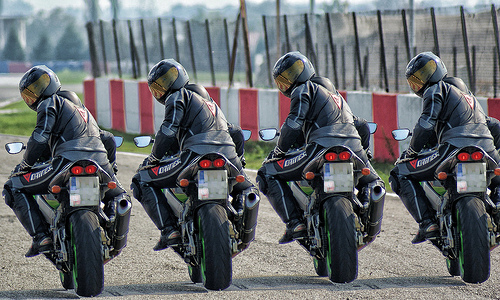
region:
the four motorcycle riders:
[19, 61, 499, 273]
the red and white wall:
[88, 74, 499, 171]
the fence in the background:
[86, 22, 496, 91]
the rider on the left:
[12, 61, 135, 288]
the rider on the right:
[393, 56, 498, 266]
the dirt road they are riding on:
[0, 133, 495, 299]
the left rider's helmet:
[19, 72, 64, 104]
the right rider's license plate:
[452, 158, 492, 198]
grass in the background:
[7, 75, 394, 189]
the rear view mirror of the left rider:
[3, 140, 24, 155]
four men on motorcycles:
[10, 40, 494, 291]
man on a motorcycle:
[17, 47, 131, 290]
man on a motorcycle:
[130, 41, 278, 287]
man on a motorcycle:
[257, 40, 392, 282]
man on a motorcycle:
[395, 28, 498, 285]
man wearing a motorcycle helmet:
[2, 56, 74, 118]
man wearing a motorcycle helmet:
[137, 45, 202, 119]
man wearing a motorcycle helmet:
[265, 45, 331, 135]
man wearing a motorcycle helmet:
[385, 35, 467, 107]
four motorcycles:
[20, 138, 495, 285]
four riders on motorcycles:
[4, 35, 496, 292]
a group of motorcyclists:
[2, 35, 494, 288]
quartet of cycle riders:
[10, 35, 498, 291]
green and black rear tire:
[60, 208, 107, 298]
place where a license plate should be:
[191, 165, 230, 204]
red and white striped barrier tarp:
[226, 87, 278, 144]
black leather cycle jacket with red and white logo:
[279, 80, 357, 146]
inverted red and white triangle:
[324, 87, 344, 111]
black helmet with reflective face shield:
[143, 56, 186, 101]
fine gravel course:
[117, 251, 179, 298]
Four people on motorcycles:
[2, 43, 497, 295]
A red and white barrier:
[79, 72, 498, 166]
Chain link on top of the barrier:
[85, 4, 498, 99]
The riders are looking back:
[13, 50, 464, 124]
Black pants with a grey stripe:
[1, 146, 81, 241]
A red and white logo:
[146, 155, 181, 176]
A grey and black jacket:
[272, 70, 363, 160]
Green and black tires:
[440, 192, 491, 283]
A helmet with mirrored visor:
[401, 47, 446, 98]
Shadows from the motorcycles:
[0, 268, 473, 298]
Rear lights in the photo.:
[200, 154, 225, 175]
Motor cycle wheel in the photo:
[193, 207, 244, 293]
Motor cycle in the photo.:
[179, 152, 246, 184]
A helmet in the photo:
[142, 44, 193, 96]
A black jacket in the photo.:
[290, 88, 355, 126]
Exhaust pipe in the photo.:
[364, 178, 393, 208]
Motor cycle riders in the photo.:
[19, 57, 496, 289]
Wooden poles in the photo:
[235, 6, 407, 62]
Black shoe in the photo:
[24, 241, 56, 262]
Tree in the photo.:
[57, 23, 82, 65]